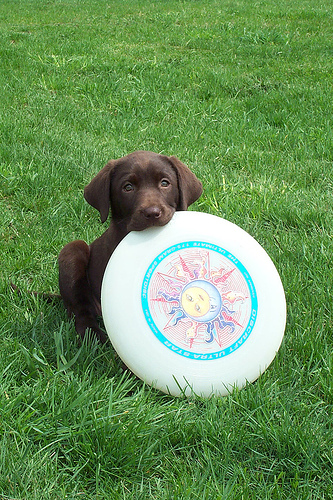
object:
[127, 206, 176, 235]
mouth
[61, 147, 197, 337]
puppy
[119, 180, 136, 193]
eye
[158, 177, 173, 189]
eye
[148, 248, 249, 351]
sun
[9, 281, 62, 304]
tail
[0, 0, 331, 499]
grass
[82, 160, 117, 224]
ear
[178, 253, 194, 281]
ray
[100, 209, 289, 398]
frisbee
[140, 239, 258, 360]
circle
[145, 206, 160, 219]
nose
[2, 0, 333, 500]
field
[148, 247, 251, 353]
logo